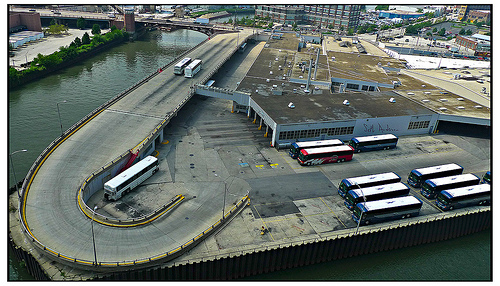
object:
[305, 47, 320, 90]
pillars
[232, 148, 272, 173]
grates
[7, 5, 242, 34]
bridge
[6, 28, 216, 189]
river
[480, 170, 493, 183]
buses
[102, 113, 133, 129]
road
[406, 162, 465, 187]
bus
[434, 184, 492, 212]
bus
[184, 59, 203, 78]
bus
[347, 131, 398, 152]
bus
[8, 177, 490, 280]
fence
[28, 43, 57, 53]
road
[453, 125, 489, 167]
ground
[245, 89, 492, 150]
building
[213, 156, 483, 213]
parking lot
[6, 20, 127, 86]
trees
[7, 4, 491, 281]
photo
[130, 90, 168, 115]
road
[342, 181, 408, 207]
buses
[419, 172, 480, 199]
buses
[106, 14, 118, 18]
bushes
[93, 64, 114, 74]
water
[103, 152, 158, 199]
bus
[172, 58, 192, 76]
bus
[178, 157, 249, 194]
road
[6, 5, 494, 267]
highway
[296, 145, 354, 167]
bus